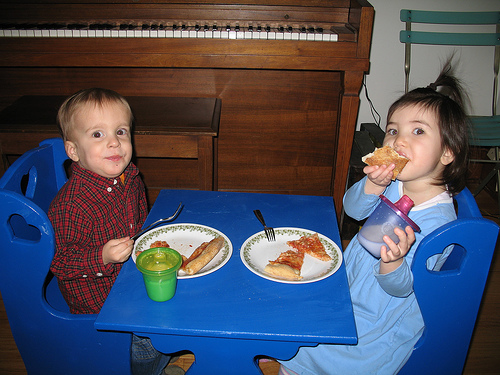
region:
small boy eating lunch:
[46, 87, 144, 322]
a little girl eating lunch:
[345, 87, 492, 369]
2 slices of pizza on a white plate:
[257, 225, 333, 290]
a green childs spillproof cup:
[132, 242, 191, 309]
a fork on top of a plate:
[252, 203, 281, 242]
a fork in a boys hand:
[102, 200, 190, 282]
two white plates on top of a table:
[127, 175, 363, 370]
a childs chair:
[402, 185, 495, 365]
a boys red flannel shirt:
[39, 166, 146, 313]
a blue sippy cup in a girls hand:
[355, 192, 424, 273]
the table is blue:
[152, 183, 358, 348]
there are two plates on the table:
[161, 221, 381, 308]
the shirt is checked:
[65, 184, 162, 296]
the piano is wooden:
[210, 70, 358, 182]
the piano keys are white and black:
[31, 15, 333, 46]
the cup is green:
[136, 255, 190, 307]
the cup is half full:
[137, 248, 192, 304]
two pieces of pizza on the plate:
[267, 212, 349, 297]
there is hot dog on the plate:
[174, 231, 230, 284]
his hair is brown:
[66, 86, 140, 135]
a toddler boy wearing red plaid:
[41, 86, 176, 316]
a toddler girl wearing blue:
[341, 61, 478, 338]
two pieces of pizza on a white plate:
[237, 226, 344, 286]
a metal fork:
[245, 201, 280, 246]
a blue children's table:
[91, 185, 366, 373]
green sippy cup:
[131, 243, 185, 307]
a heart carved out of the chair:
[4, 203, 48, 250]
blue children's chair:
[1, 132, 136, 370]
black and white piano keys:
[0, 19, 341, 41]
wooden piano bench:
[0, 78, 228, 195]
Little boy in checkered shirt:
[50, 90, 188, 374]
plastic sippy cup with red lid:
[356, 195, 423, 265]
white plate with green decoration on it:
[240, 226, 342, 286]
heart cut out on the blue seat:
[425, 241, 470, 278]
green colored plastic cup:
[136, 248, 183, 303]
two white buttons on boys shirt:
[106, 177, 118, 192]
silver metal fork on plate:
[250, 210, 280, 242]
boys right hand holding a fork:
[104, 234, 136, 270]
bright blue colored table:
[91, 186, 358, 373]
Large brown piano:
[0, 0, 375, 235]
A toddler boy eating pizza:
[23, 88, 235, 314]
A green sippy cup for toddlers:
[133, 242, 182, 307]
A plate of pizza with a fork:
[243, 202, 348, 294]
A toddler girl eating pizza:
[319, 66, 499, 373]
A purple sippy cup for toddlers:
[352, 192, 423, 278]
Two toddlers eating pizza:
[11, 68, 498, 373]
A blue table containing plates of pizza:
[125, 182, 355, 357]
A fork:
[238, 199, 279, 244]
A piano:
[6, 0, 403, 95]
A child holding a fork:
[81, 197, 189, 265]